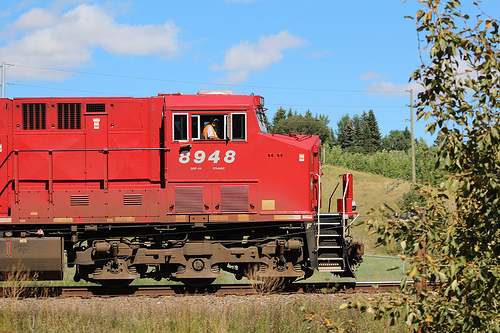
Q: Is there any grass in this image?
A: Yes, there is grass.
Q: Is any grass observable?
A: Yes, there is grass.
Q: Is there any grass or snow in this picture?
A: Yes, there is grass.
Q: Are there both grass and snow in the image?
A: No, there is grass but no snow.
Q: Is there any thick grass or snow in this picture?
A: Yes, there is thick grass.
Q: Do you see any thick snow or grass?
A: Yes, there is thick grass.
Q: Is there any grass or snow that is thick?
A: Yes, the grass is thick.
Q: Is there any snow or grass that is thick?
A: Yes, the grass is thick.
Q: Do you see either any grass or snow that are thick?
A: Yes, the grass is thick.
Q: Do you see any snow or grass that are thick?
A: Yes, the grass is thick.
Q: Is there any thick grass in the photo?
A: Yes, there is thick grass.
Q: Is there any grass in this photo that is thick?
A: Yes, there is grass that is thick.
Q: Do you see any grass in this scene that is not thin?
A: Yes, there is thick grass.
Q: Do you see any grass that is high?
A: Yes, there is high grass.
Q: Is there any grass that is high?
A: Yes, there is grass that is high.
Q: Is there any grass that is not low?
A: Yes, there is high grass.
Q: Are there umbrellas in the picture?
A: No, there are no umbrellas.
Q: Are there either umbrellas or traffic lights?
A: No, there are no umbrellas or traffic lights.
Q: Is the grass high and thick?
A: Yes, the grass is high and thick.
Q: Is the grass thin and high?
A: No, the grass is high but thick.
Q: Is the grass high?
A: Yes, the grass is high.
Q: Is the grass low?
A: No, the grass is high.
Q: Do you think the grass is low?
A: No, the grass is high.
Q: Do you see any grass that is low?
A: No, there is grass but it is high.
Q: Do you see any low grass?
A: No, there is grass but it is high.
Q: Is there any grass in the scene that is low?
A: No, there is grass but it is high.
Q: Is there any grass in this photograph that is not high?
A: No, there is grass but it is high.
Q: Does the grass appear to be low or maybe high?
A: The grass is high.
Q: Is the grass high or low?
A: The grass is high.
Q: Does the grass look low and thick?
A: No, the grass is thick but high.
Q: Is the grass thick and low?
A: No, the grass is thick but high.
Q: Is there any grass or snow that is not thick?
A: No, there is grass but it is thick.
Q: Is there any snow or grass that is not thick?
A: No, there is grass but it is thick.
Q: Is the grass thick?
A: Yes, the grass is thick.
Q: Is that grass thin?
A: No, the grass is thick.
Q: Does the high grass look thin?
A: No, the grass is thick.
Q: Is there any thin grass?
A: No, there is grass but it is thick.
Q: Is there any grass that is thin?
A: No, there is grass but it is thick.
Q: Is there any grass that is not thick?
A: No, there is grass but it is thick.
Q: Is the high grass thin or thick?
A: The grass is thick.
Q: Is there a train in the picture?
A: Yes, there is a train.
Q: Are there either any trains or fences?
A: Yes, there is a train.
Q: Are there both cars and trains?
A: No, there is a train but no cars.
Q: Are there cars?
A: No, there are no cars.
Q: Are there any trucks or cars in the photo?
A: No, there are no cars or trucks.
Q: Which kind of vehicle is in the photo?
A: The vehicle is a train.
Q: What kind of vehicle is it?
A: The vehicle is a train.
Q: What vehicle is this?
A: This is a train.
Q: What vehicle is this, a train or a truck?
A: This is a train.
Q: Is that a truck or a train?
A: That is a train.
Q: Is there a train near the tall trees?
A: Yes, there is a train near the trees.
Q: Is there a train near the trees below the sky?
A: Yes, there is a train near the trees.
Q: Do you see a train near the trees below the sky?
A: Yes, there is a train near the trees.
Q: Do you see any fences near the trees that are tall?
A: No, there is a train near the trees.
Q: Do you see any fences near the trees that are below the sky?
A: No, there is a train near the trees.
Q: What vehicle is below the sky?
A: The vehicle is a train.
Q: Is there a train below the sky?
A: Yes, there is a train below the sky.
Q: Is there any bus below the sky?
A: No, there is a train below the sky.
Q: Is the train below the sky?
A: Yes, the train is below the sky.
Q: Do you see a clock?
A: No, there are no clocks.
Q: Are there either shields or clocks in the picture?
A: No, there are no clocks or shields.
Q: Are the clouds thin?
A: Yes, the clouds are thin.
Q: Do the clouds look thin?
A: Yes, the clouds are thin.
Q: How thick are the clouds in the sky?
A: The clouds are thin.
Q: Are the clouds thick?
A: No, the clouds are thin.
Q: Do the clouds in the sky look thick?
A: No, the clouds are thin.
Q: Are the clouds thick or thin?
A: The clouds are thin.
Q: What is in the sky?
A: The clouds are in the sky.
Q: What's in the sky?
A: The clouds are in the sky.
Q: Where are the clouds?
A: The clouds are in the sky.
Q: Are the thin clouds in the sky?
A: Yes, the clouds are in the sky.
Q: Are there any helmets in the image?
A: No, there are no helmets.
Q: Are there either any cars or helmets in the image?
A: No, there are no helmets or cars.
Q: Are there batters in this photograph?
A: No, there are no batters.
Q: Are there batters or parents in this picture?
A: No, there are no batters or parents.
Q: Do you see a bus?
A: No, there are no buses.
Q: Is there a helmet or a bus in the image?
A: No, there are no buses or helmets.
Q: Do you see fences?
A: No, there are no fences.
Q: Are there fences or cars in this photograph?
A: No, there are no fences or cars.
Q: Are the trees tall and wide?
A: Yes, the trees are tall and wide.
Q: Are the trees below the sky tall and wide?
A: Yes, the trees are tall and wide.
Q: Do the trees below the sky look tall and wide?
A: Yes, the trees are tall and wide.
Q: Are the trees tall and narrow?
A: No, the trees are tall but wide.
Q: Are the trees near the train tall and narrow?
A: No, the trees are tall but wide.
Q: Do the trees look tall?
A: Yes, the trees are tall.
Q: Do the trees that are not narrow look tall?
A: Yes, the trees are tall.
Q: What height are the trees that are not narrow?
A: The trees are tall.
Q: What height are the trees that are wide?
A: The trees are tall.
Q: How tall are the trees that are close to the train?
A: The trees are tall.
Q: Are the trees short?
A: No, the trees are tall.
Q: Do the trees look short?
A: No, the trees are tall.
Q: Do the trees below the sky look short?
A: No, the trees are tall.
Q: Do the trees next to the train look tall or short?
A: The trees are tall.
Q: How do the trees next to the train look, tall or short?
A: The trees are tall.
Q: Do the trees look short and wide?
A: No, the trees are wide but tall.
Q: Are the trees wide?
A: Yes, the trees are wide.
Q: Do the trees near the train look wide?
A: Yes, the trees are wide.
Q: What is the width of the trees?
A: The trees are wide.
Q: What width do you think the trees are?
A: The trees are wide.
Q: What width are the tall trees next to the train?
A: The trees are wide.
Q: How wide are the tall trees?
A: The trees are wide.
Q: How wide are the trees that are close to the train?
A: The trees are wide.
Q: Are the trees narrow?
A: No, the trees are wide.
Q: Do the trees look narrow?
A: No, the trees are wide.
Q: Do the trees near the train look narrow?
A: No, the trees are wide.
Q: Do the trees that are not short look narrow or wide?
A: The trees are wide.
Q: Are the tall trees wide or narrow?
A: The trees are wide.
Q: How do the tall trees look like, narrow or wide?
A: The trees are wide.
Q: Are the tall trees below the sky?
A: Yes, the trees are below the sky.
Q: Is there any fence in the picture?
A: No, there are no fences.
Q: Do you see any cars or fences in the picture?
A: No, there are no fences or cars.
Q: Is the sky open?
A: Yes, the sky is open.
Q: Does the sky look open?
A: Yes, the sky is open.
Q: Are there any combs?
A: No, there are no combs.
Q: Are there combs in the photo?
A: No, there are no combs.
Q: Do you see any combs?
A: No, there are no combs.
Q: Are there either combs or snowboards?
A: No, there are no combs or snowboards.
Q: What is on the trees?
A: The leaves are on the trees.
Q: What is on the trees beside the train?
A: The leaves are on the trees.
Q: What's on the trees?
A: The leaves are on the trees.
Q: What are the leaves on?
A: The leaves are on the trees.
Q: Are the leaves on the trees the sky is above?
A: Yes, the leaves are on the trees.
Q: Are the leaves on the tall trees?
A: Yes, the leaves are on the trees.